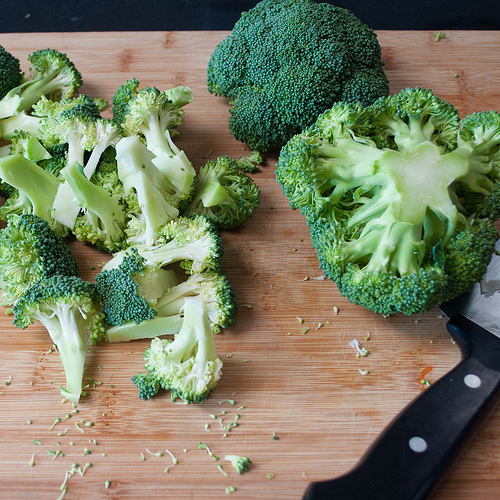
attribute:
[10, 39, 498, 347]
broccoli — pieces, cut up, chopped up, bunch, top, upside down, tiny, large, green, floret, section, debris, small, piece, dark green, light green, cut, dark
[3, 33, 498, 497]
board — wooden, cutting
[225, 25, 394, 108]
head — bushy, green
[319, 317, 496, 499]
handle — black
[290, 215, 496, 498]
knife — black, silver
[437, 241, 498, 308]
blade — shiny, silver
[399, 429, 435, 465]
dot — gray, bottom, top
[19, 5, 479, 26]
table — black, wooden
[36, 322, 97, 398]
stem — chopped, fresh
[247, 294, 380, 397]
spot — wet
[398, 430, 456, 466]
rivet — silver